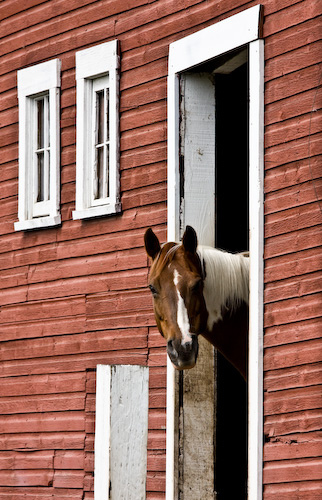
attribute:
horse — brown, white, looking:
[139, 217, 258, 393]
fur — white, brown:
[189, 234, 256, 335]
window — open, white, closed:
[19, 87, 64, 223]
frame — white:
[10, 56, 64, 236]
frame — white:
[64, 33, 125, 225]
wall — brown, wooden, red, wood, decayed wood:
[2, 0, 321, 499]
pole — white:
[91, 359, 149, 500]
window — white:
[81, 68, 117, 207]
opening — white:
[163, 39, 259, 500]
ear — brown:
[140, 220, 163, 262]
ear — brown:
[178, 223, 201, 260]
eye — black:
[147, 282, 164, 302]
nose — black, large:
[171, 336, 194, 357]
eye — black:
[189, 281, 202, 296]